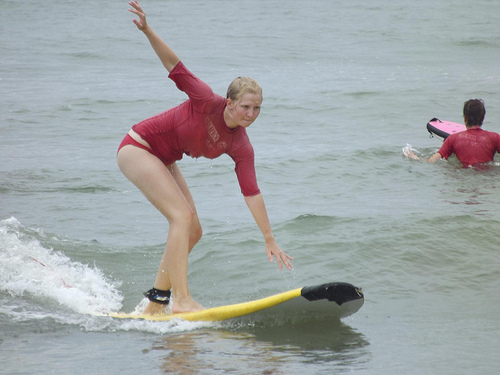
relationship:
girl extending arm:
[116, 0, 296, 312] [239, 143, 275, 249]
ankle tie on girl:
[141, 284, 169, 304] [116, 0, 296, 312]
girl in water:
[116, 0, 296, 312] [0, 0, 500, 372]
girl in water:
[116, 0, 296, 312] [68, 271, 168, 371]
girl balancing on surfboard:
[112, 0, 295, 312] [96, 275, 372, 329]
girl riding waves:
[116, 0, 296, 312] [2, 211, 127, 328]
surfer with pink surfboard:
[404, 98, 498, 166] [425, 115, 467, 139]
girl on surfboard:
[116, 0, 296, 312] [92, 280, 364, 322]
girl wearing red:
[116, 0, 296, 312] [174, 34, 212, 162]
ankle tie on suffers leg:
[141, 284, 169, 304] [146, 164, 201, 314]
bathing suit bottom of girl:
[115, 131, 155, 156] [116, 0, 296, 312]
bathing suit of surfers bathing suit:
[132, 60, 262, 197] [104, 53, 278, 205]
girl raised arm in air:
[116, 0, 296, 312] [109, 50, 138, 82]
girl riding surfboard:
[116, 0, 296, 312] [119, 274, 369, 330]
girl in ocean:
[116, 0, 296, 312] [5, 45, 102, 211]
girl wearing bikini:
[116, 0, 296, 312] [116, 130, 165, 157]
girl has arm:
[116, 0, 296, 312] [234, 157, 296, 269]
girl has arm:
[116, 0, 296, 312] [127, 2, 207, 94]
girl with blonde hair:
[116, 0, 296, 312] [224, 71, 266, 106]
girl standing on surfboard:
[116, 0, 296, 312] [136, 280, 373, 342]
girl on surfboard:
[116, 0, 296, 312] [106, 278, 366, 330]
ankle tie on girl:
[140, 284, 173, 311] [116, 0, 296, 312]